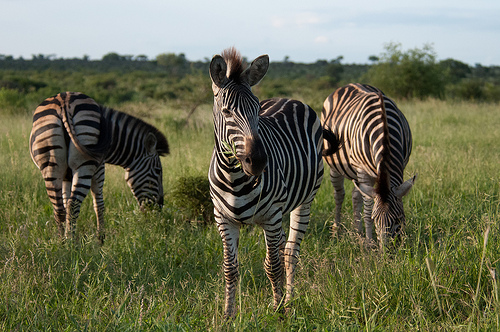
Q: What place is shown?
A: It is a field.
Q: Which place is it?
A: It is a field.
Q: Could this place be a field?
A: Yes, it is a field.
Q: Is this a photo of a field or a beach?
A: It is showing a field.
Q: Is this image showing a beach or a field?
A: It is showing a field.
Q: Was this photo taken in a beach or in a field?
A: It was taken at a field.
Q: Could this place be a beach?
A: No, it is a field.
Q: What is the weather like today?
A: It is cloudy.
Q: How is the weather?
A: It is cloudy.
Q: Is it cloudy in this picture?
A: Yes, it is cloudy.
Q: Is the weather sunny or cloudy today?
A: It is cloudy.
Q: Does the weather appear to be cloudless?
A: No, it is cloudy.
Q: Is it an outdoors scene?
A: Yes, it is outdoors.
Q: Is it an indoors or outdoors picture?
A: It is outdoors.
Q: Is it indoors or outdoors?
A: It is outdoors.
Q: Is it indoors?
A: No, it is outdoors.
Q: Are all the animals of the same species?
A: Yes, all the animals are zebras.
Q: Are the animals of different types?
A: No, all the animals are zebras.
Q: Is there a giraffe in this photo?
A: No, there are no giraffes.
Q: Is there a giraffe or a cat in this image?
A: No, there are no giraffes or cats.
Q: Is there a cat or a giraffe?
A: No, there are no giraffes or cats.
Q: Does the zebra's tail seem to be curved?
A: Yes, the tail is curved.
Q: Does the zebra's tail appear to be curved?
A: Yes, the tail is curved.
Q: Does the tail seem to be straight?
A: No, the tail is curved.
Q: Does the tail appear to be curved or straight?
A: The tail is curved.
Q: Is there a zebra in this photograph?
A: Yes, there is a zebra.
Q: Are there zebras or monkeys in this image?
A: Yes, there is a zebra.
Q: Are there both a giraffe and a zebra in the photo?
A: No, there is a zebra but no giraffes.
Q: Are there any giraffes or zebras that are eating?
A: Yes, the zebra is eating.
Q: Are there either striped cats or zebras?
A: Yes, there is a striped zebra.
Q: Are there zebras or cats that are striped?
A: Yes, the zebra is striped.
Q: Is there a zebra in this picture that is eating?
A: Yes, there is a zebra that is eating.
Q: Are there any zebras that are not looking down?
A: Yes, there is a zebra that is eating.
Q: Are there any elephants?
A: No, there are no elephants.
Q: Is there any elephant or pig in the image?
A: No, there are no elephants or pigs.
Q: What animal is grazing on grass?
A: The animal is a zebra.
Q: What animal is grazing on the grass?
A: The animal is a zebra.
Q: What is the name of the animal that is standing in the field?
A: The animal is a zebra.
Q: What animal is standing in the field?
A: The animal is a zebra.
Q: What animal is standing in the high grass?
A: The zebra is standing in the grass.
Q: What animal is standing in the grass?
A: The zebra is standing in the grass.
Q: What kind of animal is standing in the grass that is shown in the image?
A: The animal is a zebra.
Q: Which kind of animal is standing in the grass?
A: The animal is a zebra.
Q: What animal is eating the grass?
A: The zebra is eating the grass.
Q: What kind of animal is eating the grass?
A: The animal is a zebra.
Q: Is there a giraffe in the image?
A: No, there are no giraffes.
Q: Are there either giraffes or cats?
A: No, there are no giraffes or cats.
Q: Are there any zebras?
A: Yes, there is a zebra.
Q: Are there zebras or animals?
A: Yes, there is a zebra.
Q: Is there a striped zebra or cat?
A: Yes, there is a striped zebra.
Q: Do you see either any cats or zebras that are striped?
A: Yes, the zebra is striped.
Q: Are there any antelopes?
A: No, there are no antelopes.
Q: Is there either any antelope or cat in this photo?
A: No, there are no antelopes or cats.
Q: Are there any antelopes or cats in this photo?
A: No, there are no antelopes or cats.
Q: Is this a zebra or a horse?
A: This is a zebra.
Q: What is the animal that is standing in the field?
A: The animal is a zebra.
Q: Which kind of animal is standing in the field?
A: The animal is a zebra.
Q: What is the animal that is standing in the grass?
A: The animal is a zebra.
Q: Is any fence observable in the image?
A: No, there are no fences.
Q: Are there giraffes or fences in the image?
A: No, there are no fences or giraffes.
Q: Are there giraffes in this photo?
A: No, there are no giraffes.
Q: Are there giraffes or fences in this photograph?
A: No, there are no giraffes or fences.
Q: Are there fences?
A: No, there are no fences.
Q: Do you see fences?
A: No, there are no fences.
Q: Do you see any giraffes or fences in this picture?
A: No, there are no fences or giraffes.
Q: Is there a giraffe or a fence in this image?
A: No, there are no fences or giraffes.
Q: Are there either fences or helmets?
A: No, there are no fences or helmets.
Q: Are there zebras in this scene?
A: Yes, there are zebras.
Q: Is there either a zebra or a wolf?
A: Yes, there are zebras.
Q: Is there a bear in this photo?
A: No, there are no bears.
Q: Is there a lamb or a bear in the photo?
A: No, there are no bears or lambs.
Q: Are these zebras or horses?
A: These are zebras.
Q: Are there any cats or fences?
A: No, there are no fences or cats.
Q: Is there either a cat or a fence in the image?
A: No, there are no fences or cats.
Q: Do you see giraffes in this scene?
A: No, there are no giraffes.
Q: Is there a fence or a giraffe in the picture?
A: No, there are no giraffes or fences.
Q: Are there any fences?
A: No, there are no fences.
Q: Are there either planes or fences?
A: No, there are no fences or planes.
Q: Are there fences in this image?
A: No, there are no fences.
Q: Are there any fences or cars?
A: No, there are no fences or cars.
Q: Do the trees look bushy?
A: Yes, the trees are bushy.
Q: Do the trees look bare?
A: No, the trees are bushy.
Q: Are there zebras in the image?
A: Yes, there is a zebra.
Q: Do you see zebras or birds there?
A: Yes, there is a zebra.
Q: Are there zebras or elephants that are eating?
A: Yes, the zebra is eating.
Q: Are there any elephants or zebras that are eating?
A: Yes, the zebra is eating.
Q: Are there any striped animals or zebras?
A: Yes, there is a striped zebra.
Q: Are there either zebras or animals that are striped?
A: Yes, the zebra is striped.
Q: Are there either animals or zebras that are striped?
A: Yes, the zebra is striped.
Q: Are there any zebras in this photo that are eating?
A: Yes, there is a zebra that is eating.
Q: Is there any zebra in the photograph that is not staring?
A: Yes, there is a zebra that is eating.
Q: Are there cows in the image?
A: No, there are no cows.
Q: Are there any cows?
A: No, there are no cows.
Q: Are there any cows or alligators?
A: No, there are no cows or alligators.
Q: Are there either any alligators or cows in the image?
A: No, there are no cows or alligators.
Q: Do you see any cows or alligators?
A: No, there are no cows or alligators.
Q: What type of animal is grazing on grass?
A: The animal is a zebra.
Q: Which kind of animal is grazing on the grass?
A: The animal is a zebra.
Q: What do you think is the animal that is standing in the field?
A: The animal is a zebra.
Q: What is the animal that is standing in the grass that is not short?
A: The animal is a zebra.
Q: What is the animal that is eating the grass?
A: The animal is a zebra.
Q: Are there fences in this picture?
A: No, there are no fences.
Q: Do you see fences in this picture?
A: No, there are no fences.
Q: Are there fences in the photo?
A: No, there are no fences.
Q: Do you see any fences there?
A: No, there are no fences.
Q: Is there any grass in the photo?
A: Yes, there is grass.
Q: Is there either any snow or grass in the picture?
A: Yes, there is grass.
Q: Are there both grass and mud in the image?
A: No, there is grass but no mud.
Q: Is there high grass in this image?
A: Yes, there is high grass.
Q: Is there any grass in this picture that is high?
A: Yes, there is grass that is high.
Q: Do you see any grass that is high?
A: Yes, there is grass that is high.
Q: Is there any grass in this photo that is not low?
A: Yes, there is high grass.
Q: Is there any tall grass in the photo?
A: Yes, there is tall grass.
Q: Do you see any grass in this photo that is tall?
A: Yes, there is tall grass.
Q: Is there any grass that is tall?
A: Yes, there is grass that is tall.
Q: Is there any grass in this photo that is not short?
A: Yes, there is tall grass.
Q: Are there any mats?
A: No, there are no mats.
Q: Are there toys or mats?
A: No, there are no mats or toys.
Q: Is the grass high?
A: Yes, the grass is high.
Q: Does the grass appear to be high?
A: Yes, the grass is high.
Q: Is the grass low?
A: No, the grass is high.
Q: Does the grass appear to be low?
A: No, the grass is high.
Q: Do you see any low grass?
A: No, there is grass but it is high.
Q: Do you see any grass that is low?
A: No, there is grass but it is high.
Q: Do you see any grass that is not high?
A: No, there is grass but it is high.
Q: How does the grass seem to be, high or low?
A: The grass is high.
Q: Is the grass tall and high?
A: Yes, the grass is tall and high.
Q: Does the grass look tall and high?
A: Yes, the grass is tall and high.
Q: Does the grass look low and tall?
A: No, the grass is tall but high.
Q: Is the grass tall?
A: Yes, the grass is tall.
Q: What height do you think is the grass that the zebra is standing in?
A: The grass is tall.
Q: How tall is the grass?
A: The grass is tall.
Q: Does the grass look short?
A: No, the grass is tall.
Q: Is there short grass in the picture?
A: No, there is grass but it is tall.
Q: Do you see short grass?
A: No, there is grass but it is tall.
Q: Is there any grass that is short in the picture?
A: No, there is grass but it is tall.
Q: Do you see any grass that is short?
A: No, there is grass but it is tall.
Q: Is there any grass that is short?
A: No, there is grass but it is tall.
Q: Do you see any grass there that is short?
A: No, there is grass but it is tall.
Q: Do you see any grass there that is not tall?
A: No, there is grass but it is tall.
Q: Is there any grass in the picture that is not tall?
A: No, there is grass but it is tall.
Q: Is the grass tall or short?
A: The grass is tall.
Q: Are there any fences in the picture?
A: No, there are no fences.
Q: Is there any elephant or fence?
A: No, there are no fences or elephants.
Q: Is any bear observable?
A: No, there are no bears.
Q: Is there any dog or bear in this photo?
A: No, there are no bears or dogs.